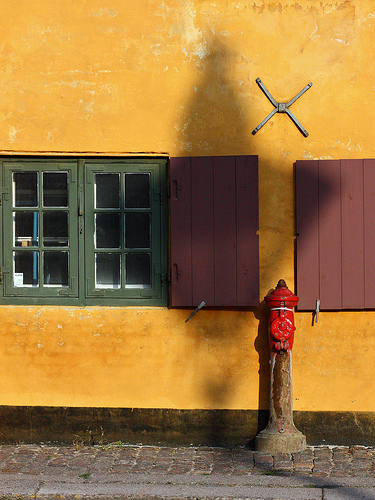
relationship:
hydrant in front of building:
[262, 274, 300, 452] [5, 229, 362, 428]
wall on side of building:
[0, 0, 370, 421] [0, 0, 369, 445]